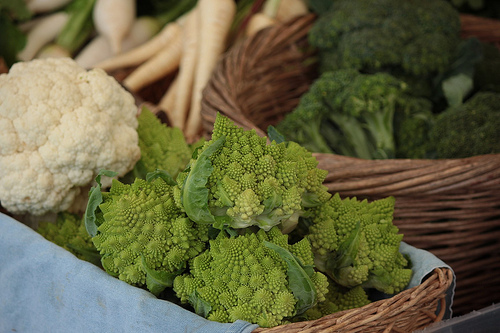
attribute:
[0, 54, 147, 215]
cauliflower — vegetables, white, fresh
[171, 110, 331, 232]
stuff — green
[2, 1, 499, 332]
two baskets — next to each other, different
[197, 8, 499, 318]
basket — brown, large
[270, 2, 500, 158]
food — in the background, fresh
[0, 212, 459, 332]
cloth — blue, light blue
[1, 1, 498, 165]
background — blurry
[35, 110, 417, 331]
brussel sprouts — fresh, light green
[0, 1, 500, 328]
vegetables — fresh, green, varieties, farm fresh, garden 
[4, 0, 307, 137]
ears of corn — fresh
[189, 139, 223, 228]
leaf — green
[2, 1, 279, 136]
parsnips — bunch